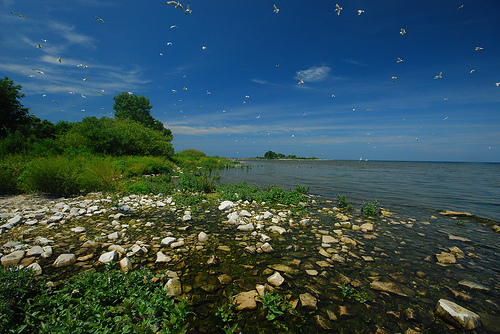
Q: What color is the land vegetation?
A: Green.